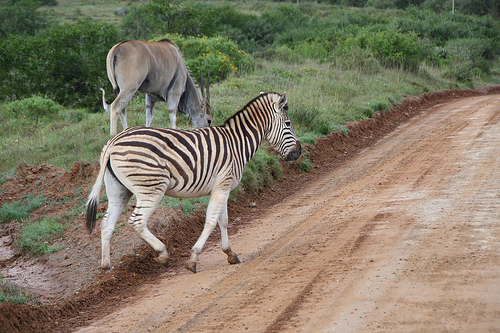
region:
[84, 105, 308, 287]
zebra walking onto a dirt road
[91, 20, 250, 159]
antelope grazing in the grass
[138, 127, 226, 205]
black and white stripes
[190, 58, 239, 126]
small pointed horns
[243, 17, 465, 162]
brush and grass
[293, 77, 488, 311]
paved dirt road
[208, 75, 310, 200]
zebra with a short black mane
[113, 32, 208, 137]
antelope with grey hair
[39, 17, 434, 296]
animals spending time outside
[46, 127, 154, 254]
long tail with black hair on the end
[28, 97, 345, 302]
zebra walking on side of road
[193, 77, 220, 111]
horns on gazelle's head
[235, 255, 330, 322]
tracks on dirt road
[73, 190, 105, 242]
tail of black and white zebra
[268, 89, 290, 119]
ear of black and white zebra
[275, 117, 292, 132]
right eye of zebra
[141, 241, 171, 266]
hoof of black and white zebra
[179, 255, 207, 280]
hoof of black and white zebra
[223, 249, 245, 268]
hoof of black and white zebra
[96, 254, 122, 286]
hoof of black and white zebra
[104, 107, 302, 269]
a zebra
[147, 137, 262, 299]
a zebra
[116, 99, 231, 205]
a zebra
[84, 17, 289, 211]
a zebra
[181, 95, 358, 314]
a zebra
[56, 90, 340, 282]
zebra on dirt road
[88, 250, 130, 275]
hoof of black and white zebra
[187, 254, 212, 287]
hoof of black and white zebra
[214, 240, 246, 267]
hoof of black and white zebra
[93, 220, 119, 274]
leg of black and white zebra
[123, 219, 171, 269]
leg of black and white zebra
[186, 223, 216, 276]
leg of black and white zebra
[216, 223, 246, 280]
leg of black and white zebra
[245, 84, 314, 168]
head of black and white zebra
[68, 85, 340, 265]
zebra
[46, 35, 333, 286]
one striped zebra and another animal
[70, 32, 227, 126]
animal that looks like a zebra without stripes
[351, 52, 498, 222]
dirt road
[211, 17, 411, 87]
green grass on the side of a road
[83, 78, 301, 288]
zebra walking down the road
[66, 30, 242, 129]
animal eating the grass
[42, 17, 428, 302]
zebra walking and another animal eating grass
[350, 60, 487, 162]
grass and dirt road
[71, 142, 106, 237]
tail of a zebra